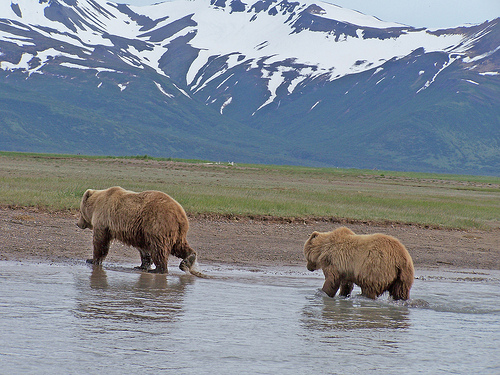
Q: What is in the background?
A: Snow covered hills.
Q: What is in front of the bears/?
A: Grass and mud.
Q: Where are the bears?
A: In water.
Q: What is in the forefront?
A: Water.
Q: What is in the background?
A: Moutain.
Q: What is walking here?
A: Bear.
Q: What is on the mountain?
A: Snow.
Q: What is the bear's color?
A: Brown.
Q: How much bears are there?
A: Two.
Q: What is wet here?
A: Bear's belly.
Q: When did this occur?
A: During the day time.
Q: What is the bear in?
A: Water.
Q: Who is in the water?
A: Two bears?.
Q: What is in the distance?
A: A mountain.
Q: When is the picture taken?
A: Daylight hours.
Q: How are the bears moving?
A: By moving appendages.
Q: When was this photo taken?
A: Daytime.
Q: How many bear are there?
A: Two.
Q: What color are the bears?
A: Brown.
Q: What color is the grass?
A: Green.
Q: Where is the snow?
A: On the mountain.